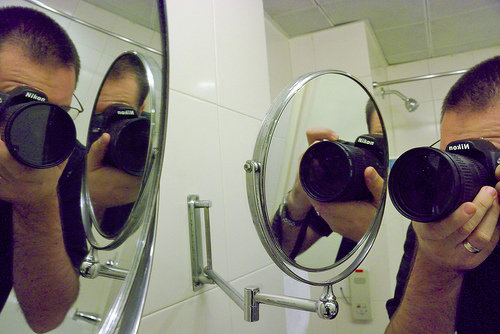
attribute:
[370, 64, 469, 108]
shower rod — metal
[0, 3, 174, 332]
mirror — metal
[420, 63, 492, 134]
hair — black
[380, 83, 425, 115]
shower head — metal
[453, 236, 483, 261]
ring — gold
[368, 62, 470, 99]
curtain rod — silver